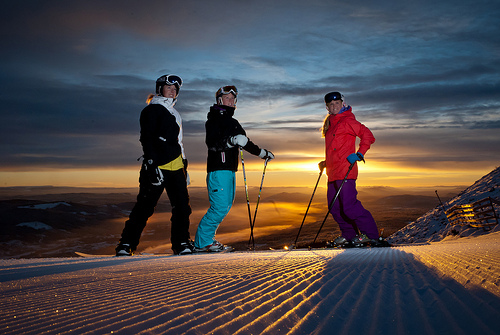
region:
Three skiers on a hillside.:
[105, 50, 420, 276]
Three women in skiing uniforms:
[115, 45, 390, 265]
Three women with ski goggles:
[120, 56, 397, 131]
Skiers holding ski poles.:
[190, 75, 392, 275]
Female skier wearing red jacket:
[291, 55, 406, 255]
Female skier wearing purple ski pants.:
[292, 60, 377, 270]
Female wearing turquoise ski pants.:
[190, 67, 275, 262]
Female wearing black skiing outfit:
[105, 50, 185, 256]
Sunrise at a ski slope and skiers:
[20, 20, 475, 285]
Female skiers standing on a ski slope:
[40, 31, 440, 276]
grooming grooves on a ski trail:
[218, 254, 435, 314]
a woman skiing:
[313, 81, 399, 250]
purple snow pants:
[319, 172, 391, 249]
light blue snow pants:
[198, 157, 244, 247]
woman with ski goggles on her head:
[317, 82, 358, 117]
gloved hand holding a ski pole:
[314, 151, 380, 258]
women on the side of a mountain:
[126, 52, 409, 266]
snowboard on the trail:
[61, 218, 206, 273]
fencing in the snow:
[432, 193, 497, 236]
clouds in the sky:
[226, 29, 320, 81]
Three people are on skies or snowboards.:
[82, 68, 417, 275]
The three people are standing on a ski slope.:
[60, 64, 395, 274]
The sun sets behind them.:
[2, 129, 484, 212]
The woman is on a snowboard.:
[65, 235, 216, 267]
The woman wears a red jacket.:
[307, 99, 377, 191]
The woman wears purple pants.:
[322, 172, 387, 238]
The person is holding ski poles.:
[228, 128, 274, 256]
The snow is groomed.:
[0, 241, 484, 333]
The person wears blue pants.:
[183, 155, 240, 257]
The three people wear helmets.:
[149, 69, 359, 126]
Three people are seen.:
[138, 72, 389, 255]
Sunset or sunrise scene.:
[133, 87, 400, 239]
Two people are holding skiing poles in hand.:
[235, 143, 368, 255]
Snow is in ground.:
[68, 272, 210, 308]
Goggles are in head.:
[159, 65, 349, 103]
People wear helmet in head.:
[158, 72, 363, 109]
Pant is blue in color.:
[201, 163, 231, 250]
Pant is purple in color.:
[321, 173, 368, 235]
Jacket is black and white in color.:
[141, 109, 188, 151]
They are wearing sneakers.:
[111, 236, 416, 261]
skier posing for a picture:
[299, 87, 387, 246]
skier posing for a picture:
[201, 75, 257, 252]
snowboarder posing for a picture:
[118, 67, 195, 252]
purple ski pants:
[323, 178, 375, 245]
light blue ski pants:
[193, 170, 231, 256]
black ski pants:
[120, 162, 195, 256]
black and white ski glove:
[145, 162, 162, 187]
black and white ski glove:
[257, 147, 274, 163]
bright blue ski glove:
[347, 151, 364, 165]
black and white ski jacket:
[202, 104, 267, 169]